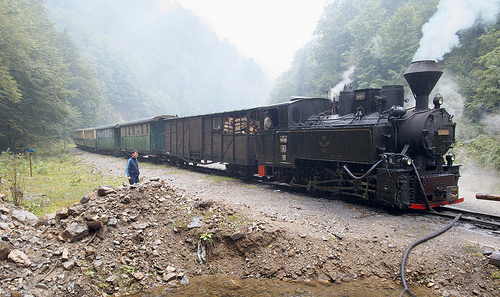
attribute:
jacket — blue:
[126, 157, 139, 173]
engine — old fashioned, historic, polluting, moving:
[259, 60, 464, 214]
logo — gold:
[317, 134, 331, 156]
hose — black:
[402, 212, 462, 294]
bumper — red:
[411, 197, 463, 210]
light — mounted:
[437, 97, 443, 106]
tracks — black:
[77, 143, 499, 233]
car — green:
[116, 114, 177, 161]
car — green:
[92, 119, 120, 157]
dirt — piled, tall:
[0, 178, 354, 296]